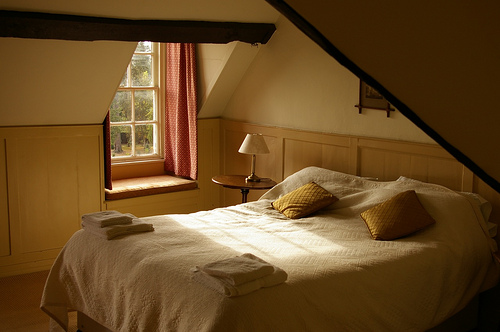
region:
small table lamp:
[230, 126, 272, 192]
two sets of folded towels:
[72, 201, 294, 301]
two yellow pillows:
[270, 179, 441, 255]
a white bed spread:
[36, 161, 497, 328]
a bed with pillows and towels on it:
[37, 158, 499, 320]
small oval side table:
[213, 168, 274, 203]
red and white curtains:
[156, 42, 198, 182]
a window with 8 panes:
[104, 41, 164, 161]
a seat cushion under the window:
[104, 166, 194, 198]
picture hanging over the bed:
[350, 71, 396, 131]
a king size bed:
[57, 167, 480, 326]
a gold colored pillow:
[361, 189, 430, 240]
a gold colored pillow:
[272, 180, 332, 211]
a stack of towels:
[195, 250, 280, 298]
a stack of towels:
[76, 206, 149, 241]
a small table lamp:
[237, 127, 267, 183]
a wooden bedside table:
[212, 168, 274, 203]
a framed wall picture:
[350, 81, 394, 115]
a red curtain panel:
[158, 42, 200, 173]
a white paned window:
[107, 44, 166, 162]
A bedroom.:
[6, 2, 498, 328]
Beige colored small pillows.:
[258, 183, 447, 242]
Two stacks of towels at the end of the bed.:
[80, 208, 292, 299]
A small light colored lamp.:
[237, 123, 267, 188]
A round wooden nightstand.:
[211, 166, 283, 218]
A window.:
[105, 45, 171, 174]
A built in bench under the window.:
[99, 167, 198, 195]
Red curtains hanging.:
[158, 43, 204, 180]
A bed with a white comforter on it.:
[54, 155, 497, 328]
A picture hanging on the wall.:
[349, 65, 405, 132]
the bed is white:
[285, 227, 324, 321]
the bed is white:
[268, 201, 339, 325]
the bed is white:
[308, 192, 360, 329]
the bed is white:
[283, 120, 357, 291]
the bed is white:
[264, 109, 391, 329]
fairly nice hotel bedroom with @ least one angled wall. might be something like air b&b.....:
[0, 1, 499, 329]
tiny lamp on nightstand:
[235, 126, 272, 186]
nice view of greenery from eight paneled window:
[107, 40, 157, 164]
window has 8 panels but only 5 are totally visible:
[107, 40, 157, 161]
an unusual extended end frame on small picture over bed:
[349, 75, 398, 125]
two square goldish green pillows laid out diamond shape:
[263, 176, 438, 251]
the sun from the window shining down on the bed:
[170, 192, 345, 262]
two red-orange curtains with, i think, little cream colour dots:
[95, 25, 201, 186]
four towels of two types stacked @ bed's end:
[75, 197, 300, 305]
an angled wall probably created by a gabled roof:
[1, 3, 286, 128]